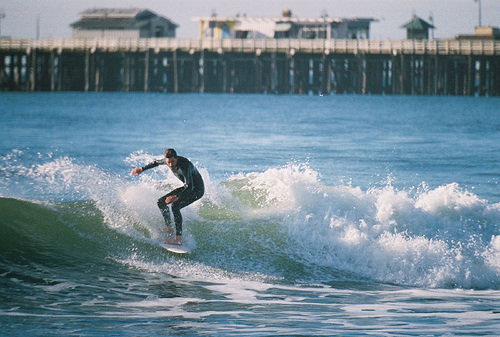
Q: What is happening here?
A: A man is surfing.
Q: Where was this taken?
A: Outside on a beach.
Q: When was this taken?
A: During the day.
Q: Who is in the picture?
A: A man.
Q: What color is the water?
A: Blue.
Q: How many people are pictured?
A: One.